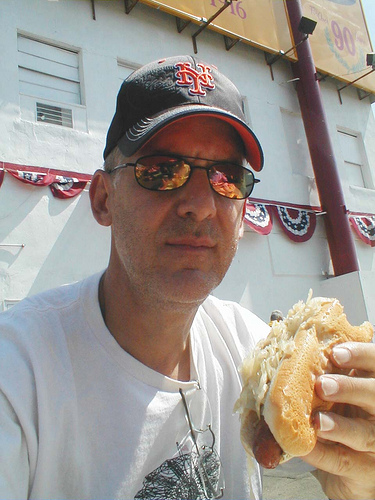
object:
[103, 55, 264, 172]
cap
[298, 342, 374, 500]
hand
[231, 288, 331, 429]
saurkraut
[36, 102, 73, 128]
conditioner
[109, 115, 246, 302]
face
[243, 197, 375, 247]
banner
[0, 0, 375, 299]
wall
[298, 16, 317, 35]
light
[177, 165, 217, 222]
nose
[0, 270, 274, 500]
shirt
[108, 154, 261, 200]
sunglasses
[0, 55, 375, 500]
man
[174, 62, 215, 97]
logo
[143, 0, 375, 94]
billboard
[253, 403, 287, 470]
hot dog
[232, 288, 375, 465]
bun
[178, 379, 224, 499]
eyeglasses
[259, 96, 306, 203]
back wall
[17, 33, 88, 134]
window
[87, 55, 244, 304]
head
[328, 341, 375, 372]
finger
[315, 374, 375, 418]
finger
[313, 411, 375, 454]
finger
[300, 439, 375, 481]
finger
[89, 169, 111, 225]
ear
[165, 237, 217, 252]
mouth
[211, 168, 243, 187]
eye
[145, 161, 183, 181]
eye